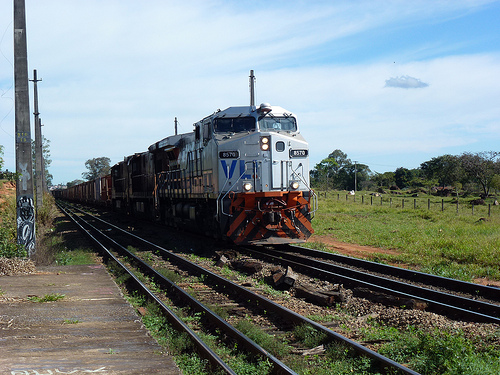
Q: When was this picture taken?
A: Daytime.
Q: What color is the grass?
A: Green.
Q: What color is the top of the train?
A: White.